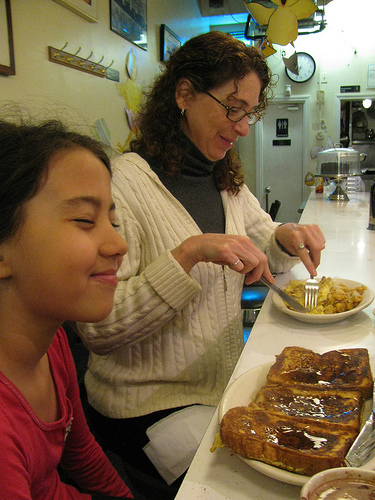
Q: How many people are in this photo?
A: 2.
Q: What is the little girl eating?
A: French toast.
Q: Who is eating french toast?
A: The girl.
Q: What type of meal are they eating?
A: Breakfast.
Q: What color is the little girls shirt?
A: Pink.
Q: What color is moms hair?
A: Brown.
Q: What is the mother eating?
A: Eggs.